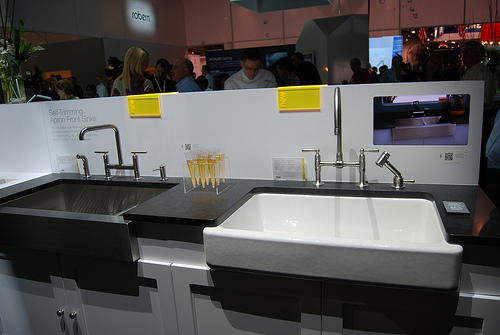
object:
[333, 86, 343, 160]
tap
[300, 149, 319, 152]
knob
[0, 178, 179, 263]
sink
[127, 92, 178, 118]
markers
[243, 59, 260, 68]
forehead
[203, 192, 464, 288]
sinks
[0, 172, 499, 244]
counter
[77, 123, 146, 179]
faucet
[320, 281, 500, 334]
cabinet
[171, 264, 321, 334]
cabinet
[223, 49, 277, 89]
man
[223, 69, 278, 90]
shirt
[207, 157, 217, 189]
shot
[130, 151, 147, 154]
knob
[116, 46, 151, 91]
hair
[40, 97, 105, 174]
sign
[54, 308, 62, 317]
nob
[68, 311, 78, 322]
nob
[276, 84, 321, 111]
post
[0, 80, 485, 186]
wall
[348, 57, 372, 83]
person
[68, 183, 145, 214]
water tap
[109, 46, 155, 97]
people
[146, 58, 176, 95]
people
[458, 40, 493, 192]
people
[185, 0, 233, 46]
cabinets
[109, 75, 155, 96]
shirt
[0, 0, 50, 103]
plant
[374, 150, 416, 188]
sprayer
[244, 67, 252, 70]
eye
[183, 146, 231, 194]
container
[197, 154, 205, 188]
test tubes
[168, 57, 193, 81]
head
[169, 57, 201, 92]
man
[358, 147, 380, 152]
knob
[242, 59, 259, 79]
face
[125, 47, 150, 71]
head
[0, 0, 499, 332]
showroom